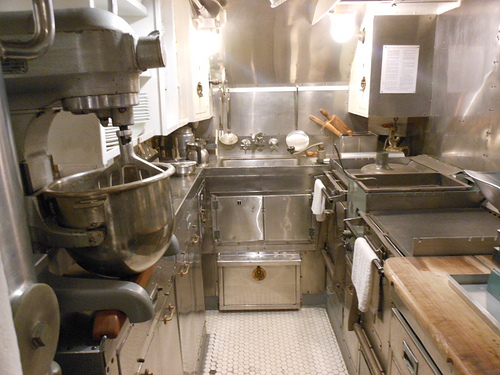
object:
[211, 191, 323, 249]
storage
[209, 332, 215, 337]
tile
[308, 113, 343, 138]
rolling pin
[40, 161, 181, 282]
bowl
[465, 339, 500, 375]
wood figure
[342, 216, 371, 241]
oven handle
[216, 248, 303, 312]
box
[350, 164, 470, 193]
sink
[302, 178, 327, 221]
towels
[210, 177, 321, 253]
door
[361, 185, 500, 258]
griddle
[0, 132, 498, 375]
counter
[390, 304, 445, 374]
drawer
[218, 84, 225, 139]
utensils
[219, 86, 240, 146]
utensils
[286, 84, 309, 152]
utensils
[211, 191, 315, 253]
cabinet doors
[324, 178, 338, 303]
stainless steel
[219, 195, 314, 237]
stainless steel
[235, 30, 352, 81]
stainless steel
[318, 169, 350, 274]
oven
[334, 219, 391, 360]
oven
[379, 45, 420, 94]
paper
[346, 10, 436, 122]
cabinet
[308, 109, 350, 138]
knife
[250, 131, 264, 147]
faucet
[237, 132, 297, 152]
faucet/sink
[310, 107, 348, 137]
handles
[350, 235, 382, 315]
towel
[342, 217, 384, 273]
handle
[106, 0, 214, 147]
cabinets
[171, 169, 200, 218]
countertops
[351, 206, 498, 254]
grill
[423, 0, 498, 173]
metal back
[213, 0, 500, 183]
wall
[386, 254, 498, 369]
countertop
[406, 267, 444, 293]
wood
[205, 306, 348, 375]
floor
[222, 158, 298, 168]
sink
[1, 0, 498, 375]
kitchen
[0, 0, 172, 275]
mixer